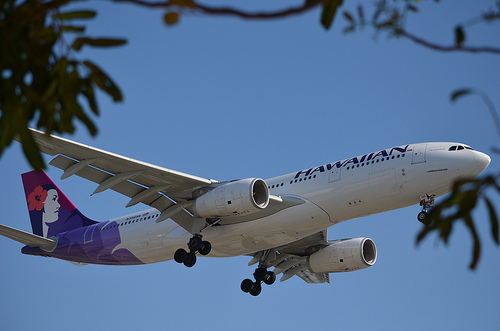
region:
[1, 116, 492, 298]
a Hawaiian Airline plane flying in the sky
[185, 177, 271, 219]
the engine of a plane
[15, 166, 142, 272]
a graphic depicting a Hawaiian woman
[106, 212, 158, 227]
the windows in the rear of a plane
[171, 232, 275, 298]
the wheels of a plane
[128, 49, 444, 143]
a clear blue sky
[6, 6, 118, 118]
the leaves of a tree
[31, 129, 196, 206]
the wing of a plane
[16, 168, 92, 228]
a colorfully decorated tail of a plane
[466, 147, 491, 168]
the nose of a plane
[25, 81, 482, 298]
large white airplane in sky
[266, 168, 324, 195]
windows on airplane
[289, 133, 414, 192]
Hawaiian painted purple on plane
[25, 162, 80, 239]
woman painted on tail of airplane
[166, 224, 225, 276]
airplane wheels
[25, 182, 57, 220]
red flowers in woman's hair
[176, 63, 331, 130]
clear blue skies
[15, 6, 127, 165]
green leaves in foreground of photo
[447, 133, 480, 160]
front windows of airplane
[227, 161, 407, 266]
two airplane propellers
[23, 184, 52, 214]
The flower in the girl's hair on the emblem on the plane.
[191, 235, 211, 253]
The front left double wheels on the plane.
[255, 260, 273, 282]
The front right double wheels of the plane.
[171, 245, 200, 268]
The back left double wheels on the plane.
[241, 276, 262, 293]
The back right double wheels on the plane.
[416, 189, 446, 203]
The front double wheels on the plane.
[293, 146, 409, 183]
The word "Hawaiian" on the side of the plane.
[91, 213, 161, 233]
The windows in the back of the plane.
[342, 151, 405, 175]
The passenger windows at the front of the plane.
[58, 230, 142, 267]
The purple design on the back of the plane.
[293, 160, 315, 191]
large jet with the letter H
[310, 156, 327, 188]
large jet with the letter A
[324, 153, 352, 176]
large jet with the letter w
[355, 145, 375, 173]
large jet with the letter i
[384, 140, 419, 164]
large jet with the letter n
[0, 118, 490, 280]
large white and blue jet plane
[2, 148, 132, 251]
beautiful picture of lady on the tail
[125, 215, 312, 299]
landing wheels on the bottom of the jet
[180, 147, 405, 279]
two engines on the large jet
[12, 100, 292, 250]
large white wing on the jet